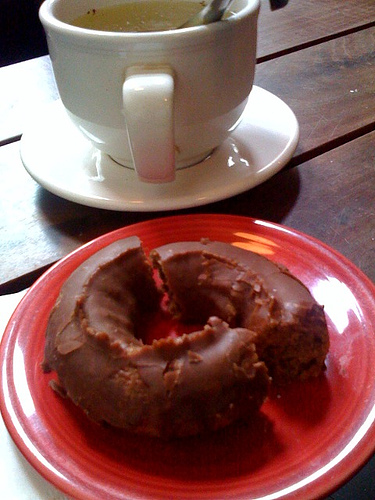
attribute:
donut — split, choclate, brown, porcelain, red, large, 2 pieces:
[57, 246, 320, 458]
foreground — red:
[16, 67, 360, 493]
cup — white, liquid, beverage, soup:
[21, 8, 276, 206]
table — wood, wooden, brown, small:
[293, 72, 348, 106]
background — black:
[6, 19, 38, 48]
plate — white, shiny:
[0, 77, 322, 234]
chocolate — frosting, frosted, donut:
[176, 250, 275, 317]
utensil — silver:
[181, 9, 236, 23]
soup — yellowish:
[93, 10, 184, 60]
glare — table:
[16, 209, 42, 234]